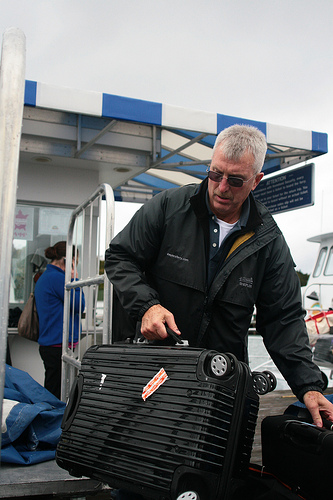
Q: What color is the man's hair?
A: Grey.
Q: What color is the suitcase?
A: Black.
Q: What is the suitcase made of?
A: Plastic.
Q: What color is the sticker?
A: Red and white.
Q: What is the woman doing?
A: Talking on the phone.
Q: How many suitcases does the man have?
A: Two.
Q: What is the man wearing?
A: A jacket.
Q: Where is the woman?
A: By the window.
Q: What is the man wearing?
A: Sunglasses.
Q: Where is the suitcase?
A: In the man's hand.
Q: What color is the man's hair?
A: Gray.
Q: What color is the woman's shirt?
A: Blue.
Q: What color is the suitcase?
A: Black.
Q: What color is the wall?
A: White.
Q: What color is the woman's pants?
A: Black.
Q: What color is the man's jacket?
A: Black.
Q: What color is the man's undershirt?
A: White.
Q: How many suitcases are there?
A: Two.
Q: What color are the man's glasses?
A: Black.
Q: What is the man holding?
A: Luggage.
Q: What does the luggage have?
A: Wheels.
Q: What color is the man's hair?
A: White.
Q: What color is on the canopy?
A: Blue and white.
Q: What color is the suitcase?
A: Black.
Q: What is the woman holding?
A: Phone.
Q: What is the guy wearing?
A: Jacket.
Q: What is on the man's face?
A: Glasses.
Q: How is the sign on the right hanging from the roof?
A: Chains.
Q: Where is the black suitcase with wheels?
A: In the man's right hand.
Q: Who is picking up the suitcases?
A: A man with a black jacket.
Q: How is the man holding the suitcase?
A: With his right hand.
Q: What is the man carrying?
A: Luggage.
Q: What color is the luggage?
A: Black.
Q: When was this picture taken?
A: Daytime.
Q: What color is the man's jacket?
A: Black.